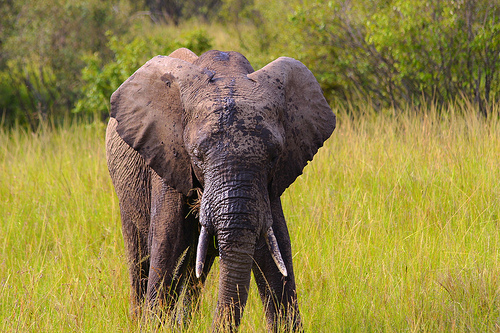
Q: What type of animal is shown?
A: Elephant.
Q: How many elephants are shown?
A: 1.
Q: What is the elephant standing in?
A: Grass.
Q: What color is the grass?
A: Yellow.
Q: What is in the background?
A: Trees.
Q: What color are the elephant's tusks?
A: White.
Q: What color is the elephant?
A: Gray and brown.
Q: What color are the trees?
A: Green.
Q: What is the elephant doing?
A: Walking.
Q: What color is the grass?
A: Green.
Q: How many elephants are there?
A: One.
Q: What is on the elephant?
A: Mud.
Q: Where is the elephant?
A: In the grass.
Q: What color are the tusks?
A: White.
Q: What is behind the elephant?
A: Trees.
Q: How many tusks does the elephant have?
A: Two.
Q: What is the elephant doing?
A: Standing.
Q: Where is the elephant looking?
A: Down at the ground.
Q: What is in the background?
A: Trees.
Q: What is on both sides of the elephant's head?
A: Ears.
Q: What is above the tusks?
A: The trunk.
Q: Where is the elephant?
A: In a field.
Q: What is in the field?
A: Tall grass.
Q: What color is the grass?
A: Green and brown.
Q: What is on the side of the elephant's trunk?
A: Tusks.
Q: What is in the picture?
A: An elephant.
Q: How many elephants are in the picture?
A: 1.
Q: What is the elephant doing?
A: Standing in grass.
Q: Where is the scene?
A: In a grassy area.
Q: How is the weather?
A: Sunny.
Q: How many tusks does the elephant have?
A: 2.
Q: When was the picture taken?
A: Daytime.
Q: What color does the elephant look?
A: Brown.